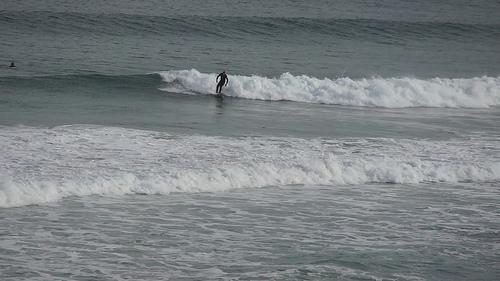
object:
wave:
[146, 67, 500, 109]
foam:
[153, 67, 499, 108]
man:
[214, 71, 229, 94]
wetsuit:
[215, 73, 229, 93]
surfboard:
[213, 92, 224, 97]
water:
[0, 1, 499, 280]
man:
[9, 62, 16, 68]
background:
[0, 0, 500, 281]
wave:
[0, 123, 499, 208]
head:
[9, 62, 17, 68]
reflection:
[0, 0, 499, 61]